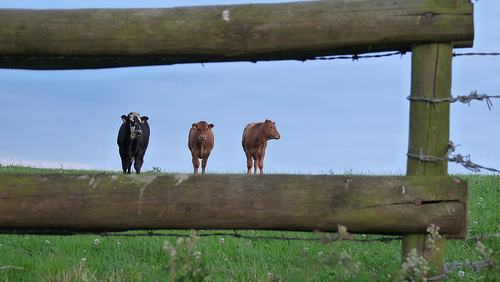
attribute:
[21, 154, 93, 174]
cloud — white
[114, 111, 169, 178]
cow — black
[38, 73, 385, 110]
sky — clear, blue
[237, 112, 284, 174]
cow — brown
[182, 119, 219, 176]
cow — brown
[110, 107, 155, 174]
cow — one, black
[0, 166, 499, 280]
grass — green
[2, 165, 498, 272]
field — grass, green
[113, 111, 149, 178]
cow — black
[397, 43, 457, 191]
pole — wood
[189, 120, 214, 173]
cow — brown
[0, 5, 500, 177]
sky — clear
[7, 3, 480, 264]
gate — wooden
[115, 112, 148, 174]
cow — black, white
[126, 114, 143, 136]
face — black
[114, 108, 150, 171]
cow — black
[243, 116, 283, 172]
cow — brown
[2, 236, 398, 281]
grass — short, green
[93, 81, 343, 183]
cow — black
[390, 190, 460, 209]
slit — black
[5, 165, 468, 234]
post — slit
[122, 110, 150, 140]
head — black, white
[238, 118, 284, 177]
cow — brown